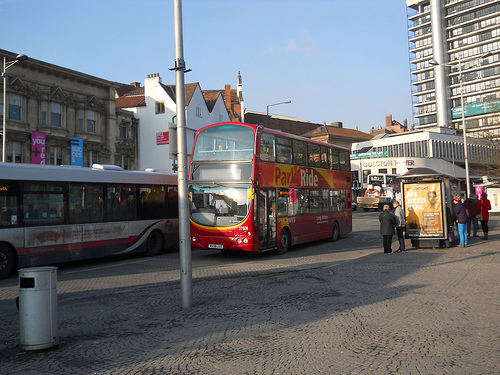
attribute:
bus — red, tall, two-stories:
[248, 133, 289, 250]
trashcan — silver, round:
[16, 261, 72, 350]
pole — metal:
[177, 165, 190, 331]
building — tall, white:
[415, 4, 431, 126]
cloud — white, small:
[281, 38, 316, 55]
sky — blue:
[68, 16, 152, 78]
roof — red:
[304, 118, 366, 137]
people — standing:
[451, 184, 493, 254]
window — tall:
[192, 132, 249, 170]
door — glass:
[252, 185, 277, 246]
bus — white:
[0, 165, 182, 260]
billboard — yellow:
[273, 154, 330, 192]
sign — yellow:
[403, 184, 453, 245]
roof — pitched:
[188, 78, 238, 128]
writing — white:
[407, 190, 424, 206]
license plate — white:
[205, 242, 225, 252]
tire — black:
[323, 220, 349, 242]